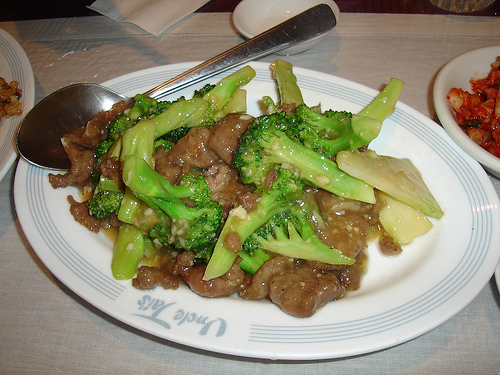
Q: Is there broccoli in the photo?
A: Yes, there is broccoli.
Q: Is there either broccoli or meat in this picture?
A: Yes, there is broccoli.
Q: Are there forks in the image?
A: No, there are no forks.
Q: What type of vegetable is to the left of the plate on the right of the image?
A: The vegetable is broccoli.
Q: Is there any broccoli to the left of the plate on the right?
A: Yes, there is broccoli to the left of the plate.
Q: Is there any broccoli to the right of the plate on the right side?
A: No, the broccoli is to the left of the plate.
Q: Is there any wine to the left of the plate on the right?
A: No, there is broccoli to the left of the plate.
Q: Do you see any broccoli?
A: Yes, there is broccoli.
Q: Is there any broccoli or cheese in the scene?
A: Yes, there is broccoli.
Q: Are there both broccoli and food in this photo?
A: Yes, there are both broccoli and food.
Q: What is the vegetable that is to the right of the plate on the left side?
A: The vegetable is broccoli.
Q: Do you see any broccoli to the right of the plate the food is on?
A: Yes, there is broccoli to the right of the plate.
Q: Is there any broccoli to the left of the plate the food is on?
A: No, the broccoli is to the right of the plate.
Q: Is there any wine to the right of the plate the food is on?
A: No, there is broccoli to the right of the plate.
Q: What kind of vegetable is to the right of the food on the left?
A: The vegetable is broccoli.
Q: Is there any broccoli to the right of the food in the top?
A: Yes, there is broccoli to the right of the food.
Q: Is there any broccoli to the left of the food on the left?
A: No, the broccoli is to the right of the food.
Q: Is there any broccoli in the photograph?
A: Yes, there is broccoli.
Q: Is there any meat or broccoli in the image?
A: Yes, there is broccoli.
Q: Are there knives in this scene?
A: No, there are no knives.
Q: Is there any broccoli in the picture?
A: Yes, there is broccoli.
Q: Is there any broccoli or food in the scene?
A: Yes, there is broccoli.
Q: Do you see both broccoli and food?
A: Yes, there are both broccoli and food.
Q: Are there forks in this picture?
A: No, there are no forks.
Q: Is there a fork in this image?
A: No, there are no forks.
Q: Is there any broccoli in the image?
A: Yes, there is broccoli.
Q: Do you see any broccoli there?
A: Yes, there is broccoli.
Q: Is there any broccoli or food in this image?
A: Yes, there is broccoli.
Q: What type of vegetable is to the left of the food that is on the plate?
A: The vegetable is broccoli.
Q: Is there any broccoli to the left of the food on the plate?
A: Yes, there is broccoli to the left of the food.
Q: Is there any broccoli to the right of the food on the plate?
A: No, the broccoli is to the left of the food.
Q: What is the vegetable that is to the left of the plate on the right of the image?
A: The vegetable is broccoli.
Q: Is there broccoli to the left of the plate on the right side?
A: Yes, there is broccoli to the left of the plate.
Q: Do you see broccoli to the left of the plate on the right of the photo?
A: Yes, there is broccoli to the left of the plate.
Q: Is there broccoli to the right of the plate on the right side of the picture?
A: No, the broccoli is to the left of the plate.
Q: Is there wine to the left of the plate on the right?
A: No, there is broccoli to the left of the plate.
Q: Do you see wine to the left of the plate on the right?
A: No, there is broccoli to the left of the plate.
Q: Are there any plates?
A: Yes, there is a plate.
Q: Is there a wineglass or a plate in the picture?
A: Yes, there is a plate.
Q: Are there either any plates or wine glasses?
A: Yes, there is a plate.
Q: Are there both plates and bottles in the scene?
A: No, there is a plate but no bottles.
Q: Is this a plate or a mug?
A: This is a plate.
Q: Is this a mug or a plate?
A: This is a plate.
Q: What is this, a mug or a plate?
A: This is a plate.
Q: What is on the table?
A: The plate is on the table.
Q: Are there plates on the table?
A: Yes, there is a plate on the table.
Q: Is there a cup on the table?
A: No, there is a plate on the table.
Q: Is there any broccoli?
A: Yes, there is broccoli.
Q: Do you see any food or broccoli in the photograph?
A: Yes, there is broccoli.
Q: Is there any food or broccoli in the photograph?
A: Yes, there is broccoli.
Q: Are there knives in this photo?
A: No, there are no knives.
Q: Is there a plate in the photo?
A: Yes, there is a plate.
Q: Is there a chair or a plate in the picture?
A: Yes, there is a plate.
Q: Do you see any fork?
A: No, there are no forks.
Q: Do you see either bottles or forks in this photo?
A: No, there are no forks or bottles.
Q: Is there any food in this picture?
A: Yes, there is food.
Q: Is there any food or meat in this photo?
A: Yes, there is food.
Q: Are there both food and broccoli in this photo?
A: Yes, there are both food and broccoli.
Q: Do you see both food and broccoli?
A: Yes, there are both food and broccoli.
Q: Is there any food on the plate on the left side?
A: Yes, there is food on the plate.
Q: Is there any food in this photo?
A: Yes, there is food.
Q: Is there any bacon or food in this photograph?
A: Yes, there is food.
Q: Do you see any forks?
A: No, there are no forks.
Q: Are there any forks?
A: No, there are no forks.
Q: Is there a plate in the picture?
A: Yes, there is a plate.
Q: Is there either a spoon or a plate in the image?
A: Yes, there is a plate.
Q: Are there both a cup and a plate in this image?
A: No, there is a plate but no cups.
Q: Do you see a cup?
A: No, there are no cups.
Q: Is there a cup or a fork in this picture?
A: No, there are no cups or forks.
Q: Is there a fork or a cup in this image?
A: No, there are no cups or forks.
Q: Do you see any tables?
A: Yes, there is a table.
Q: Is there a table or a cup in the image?
A: Yes, there is a table.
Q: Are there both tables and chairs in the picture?
A: No, there is a table but no chairs.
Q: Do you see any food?
A: Yes, there is food.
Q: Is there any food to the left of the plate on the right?
A: Yes, there is food to the left of the plate.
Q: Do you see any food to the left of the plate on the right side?
A: Yes, there is food to the left of the plate.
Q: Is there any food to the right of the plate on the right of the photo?
A: No, the food is to the left of the plate.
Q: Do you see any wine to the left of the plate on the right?
A: No, there is food to the left of the plate.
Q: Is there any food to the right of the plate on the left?
A: Yes, there is food to the right of the plate.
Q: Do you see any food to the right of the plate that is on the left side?
A: Yes, there is food to the right of the plate.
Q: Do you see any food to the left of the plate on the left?
A: No, the food is to the right of the plate.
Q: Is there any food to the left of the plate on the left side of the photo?
A: No, the food is to the right of the plate.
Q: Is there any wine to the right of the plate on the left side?
A: No, there is food to the right of the plate.